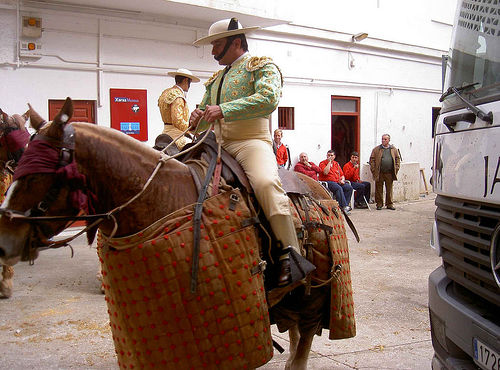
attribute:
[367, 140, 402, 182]
coat — brown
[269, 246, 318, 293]
foot — in a stirrup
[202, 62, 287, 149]
jacket — light green, yellow printed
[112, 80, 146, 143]
sign — red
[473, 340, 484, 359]
license plate — white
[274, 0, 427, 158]
building — white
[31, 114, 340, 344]
horse — brown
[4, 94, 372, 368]
horse — decorated, brown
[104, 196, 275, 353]
cloth — thick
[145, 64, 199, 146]
rider — another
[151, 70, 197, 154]
jacket — golden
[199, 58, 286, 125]
jacket — green, ceremonial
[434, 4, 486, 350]
truck — big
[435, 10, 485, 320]
bus — big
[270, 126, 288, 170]
person — looking on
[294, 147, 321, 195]
person — looking on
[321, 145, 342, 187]
person — looking on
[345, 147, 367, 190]
person — looking on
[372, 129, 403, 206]
person — looking on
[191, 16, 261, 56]
hat — wide brim, white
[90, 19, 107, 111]
pipe — metal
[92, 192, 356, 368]
blanket — decorative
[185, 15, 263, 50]
hat — white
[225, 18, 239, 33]
trim — black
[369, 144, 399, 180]
jacket — brown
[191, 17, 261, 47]
hat — white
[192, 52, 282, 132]
jacket — green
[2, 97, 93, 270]
head — brown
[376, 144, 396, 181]
shirt — gray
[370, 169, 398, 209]
pants — brown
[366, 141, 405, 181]
jacket — brown